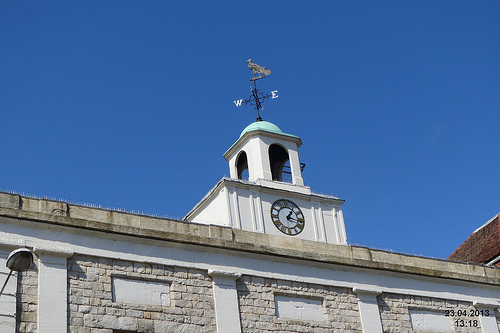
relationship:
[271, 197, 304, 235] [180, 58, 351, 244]
clock on tower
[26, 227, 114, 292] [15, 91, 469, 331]
shadow on building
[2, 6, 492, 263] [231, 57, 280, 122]
sky on vane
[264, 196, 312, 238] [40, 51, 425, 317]
clock on sky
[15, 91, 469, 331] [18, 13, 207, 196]
building on sky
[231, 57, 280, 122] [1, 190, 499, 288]
vane on ledge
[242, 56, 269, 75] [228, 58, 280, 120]
bird on weather vane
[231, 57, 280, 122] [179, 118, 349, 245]
vane on tower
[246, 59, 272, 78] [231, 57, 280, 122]
bird on vane